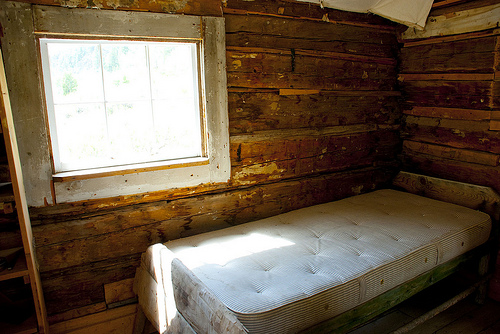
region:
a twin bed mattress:
[162, 152, 494, 324]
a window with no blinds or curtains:
[24, 31, 222, 186]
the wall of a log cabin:
[398, 32, 497, 193]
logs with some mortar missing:
[225, 73, 395, 104]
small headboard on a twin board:
[393, 155, 493, 213]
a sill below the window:
[53, 151, 211, 184]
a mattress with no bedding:
[166, 178, 486, 329]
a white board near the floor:
[97, 273, 155, 312]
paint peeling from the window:
[19, 196, 56, 213]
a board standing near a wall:
[0, 54, 50, 315]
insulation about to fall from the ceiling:
[303, 0, 435, 34]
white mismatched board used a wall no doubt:
[398, 2, 498, 42]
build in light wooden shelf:
[0, 49, 50, 331]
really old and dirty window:
[44, 38, 206, 173]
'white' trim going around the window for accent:
[0, 0, 230, 208]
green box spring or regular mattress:
[285, 238, 497, 332]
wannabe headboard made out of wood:
[388, 168, 494, 213]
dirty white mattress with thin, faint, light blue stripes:
[160, 185, 490, 331]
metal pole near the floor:
[395, 273, 485, 330]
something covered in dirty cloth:
[130, 241, 251, 332]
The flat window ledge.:
[45, 145, 266, 192]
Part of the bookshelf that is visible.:
[12, 55, 50, 332]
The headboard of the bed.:
[390, 160, 496, 229]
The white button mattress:
[104, 180, 489, 326]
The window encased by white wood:
[5, 0, 241, 205]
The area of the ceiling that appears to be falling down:
[353, 2, 460, 54]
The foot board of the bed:
[127, 245, 241, 325]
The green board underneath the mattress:
[270, 244, 492, 329]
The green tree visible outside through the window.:
[55, 69, 85, 107]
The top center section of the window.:
[94, 32, 160, 127]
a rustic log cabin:
[24, 0, 499, 332]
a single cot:
[161, 168, 495, 315]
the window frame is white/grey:
[11, 5, 256, 205]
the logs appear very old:
[276, 50, 363, 160]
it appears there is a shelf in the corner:
[1, 43, 48, 332]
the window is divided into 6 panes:
[47, 36, 217, 179]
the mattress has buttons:
[181, 201, 473, 288]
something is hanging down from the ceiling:
[318, 0, 442, 33]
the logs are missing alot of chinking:
[248, 82, 372, 99]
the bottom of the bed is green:
[334, 277, 492, 332]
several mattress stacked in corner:
[136, 174, 491, 327]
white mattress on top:
[156, 188, 488, 332]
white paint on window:
[1, 19, 231, 206]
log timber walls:
[3, 17, 499, 321]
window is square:
[35, 29, 207, 176]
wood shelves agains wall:
[0, 48, 50, 333]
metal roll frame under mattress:
[352, 263, 497, 333]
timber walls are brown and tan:
[0, 7, 499, 331]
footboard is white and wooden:
[121, 243, 246, 332]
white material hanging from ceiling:
[299, 0, 441, 30]